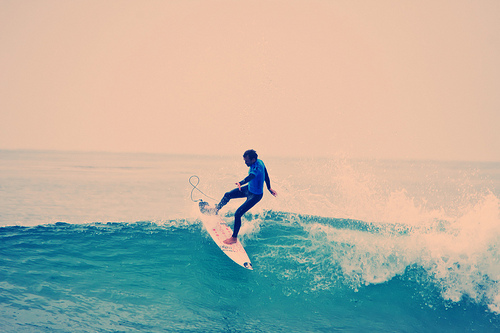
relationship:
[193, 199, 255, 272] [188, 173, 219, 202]
surfboard has cord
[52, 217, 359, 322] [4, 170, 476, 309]
ocean spray on ocean wave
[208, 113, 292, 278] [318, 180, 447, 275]
surfer on wave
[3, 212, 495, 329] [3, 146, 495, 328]
wave in ocean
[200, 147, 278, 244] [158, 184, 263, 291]
he on board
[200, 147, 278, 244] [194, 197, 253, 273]
he on board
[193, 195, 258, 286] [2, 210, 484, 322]
surfboard on ocean